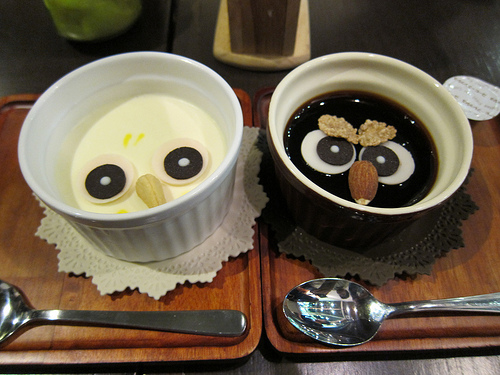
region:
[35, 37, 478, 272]
two bowls of soup with a character design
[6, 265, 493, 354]
two silver spoons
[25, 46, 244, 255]
white ceramic bowl of soup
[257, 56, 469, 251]
brown ceramic bowl of soup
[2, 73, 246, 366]
square wooden plate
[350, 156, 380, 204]
almod used as nose of character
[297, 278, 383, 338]
reflection can be seen in spoon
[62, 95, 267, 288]
white doily under bowl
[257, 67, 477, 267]
black doily under bowl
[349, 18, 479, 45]
solid black table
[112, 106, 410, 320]
This is a dessert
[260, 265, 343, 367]
This is a utensil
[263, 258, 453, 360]
This is a spoon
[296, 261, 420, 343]
This is made of metal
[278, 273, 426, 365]
The spoon is silver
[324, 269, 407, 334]
The spoon is made of steel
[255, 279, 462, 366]
This is a tray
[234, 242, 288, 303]
The tray is made of wood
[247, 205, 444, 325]
This is a doilie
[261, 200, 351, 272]
This is a ramaken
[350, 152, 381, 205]
The almond in the coffee cup.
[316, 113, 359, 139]
The cereal flake on the left side in the black cup.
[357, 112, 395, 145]
The cereal flake on the right side in the black cup.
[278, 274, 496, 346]
The spoon on the right.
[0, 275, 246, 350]
The spoon on the left.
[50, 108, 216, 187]
The white cream in the white cup.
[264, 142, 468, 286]
The black paper under the black cup.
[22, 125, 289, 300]
The white paper under the white cup.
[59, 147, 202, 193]
The eyes in the white cup.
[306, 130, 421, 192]
The eyes in the black cup.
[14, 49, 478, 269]
Two cups of coffee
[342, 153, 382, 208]
A peanut in the coffee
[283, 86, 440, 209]
A face in the coffee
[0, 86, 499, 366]
Two brown wooden plates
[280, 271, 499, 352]
Silver spoon on plate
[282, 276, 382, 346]
Reflections in the spoon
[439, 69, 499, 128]
A round cream packet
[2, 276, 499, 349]
Two spoons are silver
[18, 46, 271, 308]
White cup on white cloth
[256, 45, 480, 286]
Black cup on black cloth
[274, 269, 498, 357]
a silver spoon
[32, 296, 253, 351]
handle of a silver spoon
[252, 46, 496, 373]
a bowl and a spoon on a tray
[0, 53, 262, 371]
a brown tray under a bowl and a spoon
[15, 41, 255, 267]
a white bowl with cream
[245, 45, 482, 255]
a brown bowl with chocolate cream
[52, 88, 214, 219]
two eyes on white cream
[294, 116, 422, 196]
two eyes on chocolate cream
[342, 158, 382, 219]
an almond over chocolate cream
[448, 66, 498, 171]
a lid over atray